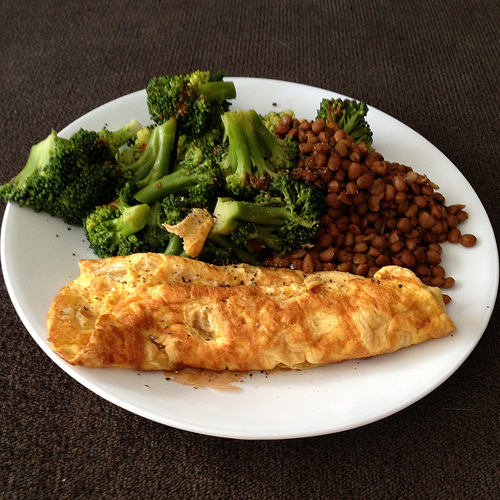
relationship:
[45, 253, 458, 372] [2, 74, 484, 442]
omelette lying on top of plate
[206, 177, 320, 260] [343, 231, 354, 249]
broccoli lying near bean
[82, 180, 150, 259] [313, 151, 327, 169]
broccoli lying near bean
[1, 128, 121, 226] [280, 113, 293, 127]
broccoli lying near bean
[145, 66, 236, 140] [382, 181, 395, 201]
broccoli lying near bean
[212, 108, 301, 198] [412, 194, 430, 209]
broccoli lying near bean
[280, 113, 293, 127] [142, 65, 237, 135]
bean lying near broccoli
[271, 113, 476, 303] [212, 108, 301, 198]
bean lying near broccoli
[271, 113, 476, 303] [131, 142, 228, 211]
bean lying near broccoli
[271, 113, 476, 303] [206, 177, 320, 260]
bean lying near broccoli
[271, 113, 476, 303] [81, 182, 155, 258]
bean lying near broccoli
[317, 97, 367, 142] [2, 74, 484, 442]
broccoli on plate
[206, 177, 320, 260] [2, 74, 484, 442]
broccoli on plate